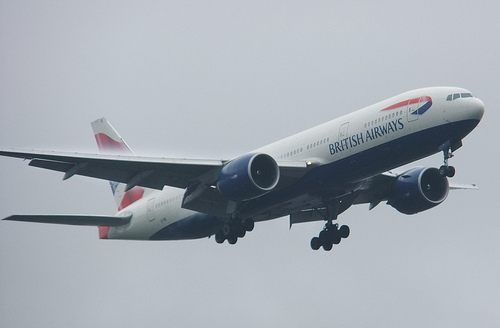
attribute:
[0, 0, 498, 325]
sky — overcast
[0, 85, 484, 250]
plane — blue, large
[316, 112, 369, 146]
door — middle, right side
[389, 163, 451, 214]
engine — blue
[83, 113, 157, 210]
tail — red, white, blue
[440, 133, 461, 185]
landing gear — for landing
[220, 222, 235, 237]
wheel — dropped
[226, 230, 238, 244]
wheel — dropped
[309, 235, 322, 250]
wheel — dropped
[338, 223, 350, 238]
wheel — dropped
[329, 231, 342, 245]
wheel — dropped